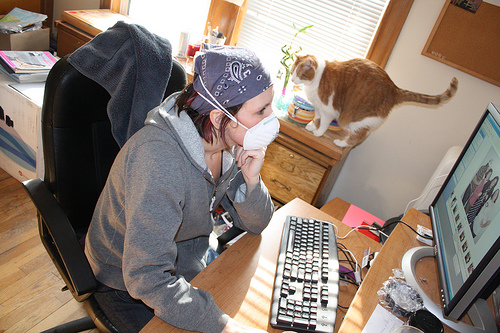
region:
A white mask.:
[187, 72, 282, 149]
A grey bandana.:
[189, 44, 274, 129]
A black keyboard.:
[269, 197, 338, 331]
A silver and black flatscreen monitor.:
[397, 99, 498, 329]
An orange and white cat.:
[289, 52, 457, 167]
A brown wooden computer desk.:
[129, 193, 496, 330]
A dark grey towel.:
[69, 20, 171, 149]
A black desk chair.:
[23, 53, 213, 330]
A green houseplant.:
[275, 19, 312, 103]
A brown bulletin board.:
[418, 1, 498, 93]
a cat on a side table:
[285, 43, 472, 152]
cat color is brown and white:
[285, 40, 468, 150]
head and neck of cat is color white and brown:
[287, 43, 329, 92]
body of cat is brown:
[321, 58, 404, 120]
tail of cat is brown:
[401, 67, 468, 113]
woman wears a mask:
[76, 35, 285, 332]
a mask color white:
[239, 107, 284, 161]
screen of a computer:
[424, 101, 499, 331]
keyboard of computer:
[260, 205, 347, 330]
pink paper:
[341, 195, 394, 243]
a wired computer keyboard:
[270, 213, 337, 331]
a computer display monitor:
[430, 105, 499, 317]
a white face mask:
[186, 65, 280, 153]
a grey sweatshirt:
[77, 89, 271, 331]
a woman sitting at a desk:
[84, 39, 277, 331]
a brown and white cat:
[284, 46, 459, 148]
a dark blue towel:
[69, 18, 172, 139]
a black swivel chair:
[23, 42, 188, 332]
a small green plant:
[271, 18, 315, 119]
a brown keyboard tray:
[143, 195, 378, 332]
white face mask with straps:
[193, 74, 280, 155]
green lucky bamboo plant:
[280, 19, 313, 96]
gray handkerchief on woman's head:
[188, 52, 270, 115]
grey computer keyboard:
[269, 212, 340, 331]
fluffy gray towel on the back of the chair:
[61, 21, 173, 142]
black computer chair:
[21, 57, 189, 332]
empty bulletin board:
[421, 0, 499, 88]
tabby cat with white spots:
[288, 51, 460, 151]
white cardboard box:
[1, 74, 46, 193]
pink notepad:
[341, 202, 384, 239]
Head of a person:
[179, 28, 289, 173]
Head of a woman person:
[193, 40, 295, 174]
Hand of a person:
[117, 146, 274, 331]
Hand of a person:
[227, 140, 283, 239]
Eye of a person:
[255, 103, 271, 119]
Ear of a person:
[204, 106, 234, 133]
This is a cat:
[283, 39, 464, 153]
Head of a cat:
[283, 45, 323, 94]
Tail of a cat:
[395, 68, 461, 111]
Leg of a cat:
[315, 103, 334, 155]